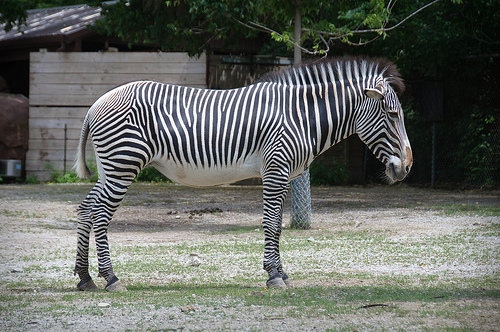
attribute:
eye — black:
[385, 105, 399, 122]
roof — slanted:
[0, 2, 120, 47]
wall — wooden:
[30, 53, 97, 110]